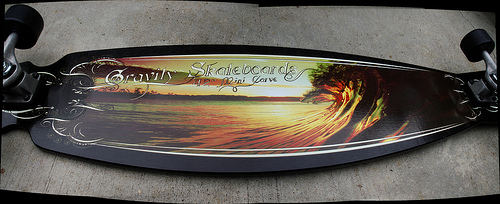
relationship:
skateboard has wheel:
[3, 4, 496, 176] [459, 26, 495, 63]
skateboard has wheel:
[3, 4, 496, 176] [4, 5, 45, 47]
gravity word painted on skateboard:
[105, 68, 181, 86] [3, 4, 496, 176]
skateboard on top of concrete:
[3, 4, 496, 176] [2, 3, 499, 203]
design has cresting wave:
[65, 57, 437, 138] [302, 62, 405, 147]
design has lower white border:
[65, 57, 437, 138] [43, 116, 473, 162]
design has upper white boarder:
[65, 57, 437, 138] [68, 50, 429, 94]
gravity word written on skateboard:
[105, 68, 181, 86] [3, 4, 496, 176]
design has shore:
[65, 57, 437, 138] [86, 90, 320, 104]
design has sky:
[65, 57, 437, 138] [85, 57, 338, 99]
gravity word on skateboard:
[105, 68, 181, 86] [3, 4, 496, 176]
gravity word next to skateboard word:
[105, 68, 181, 86] [185, 61, 302, 81]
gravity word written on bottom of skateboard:
[105, 68, 181, 86] [3, 4, 496, 176]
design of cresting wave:
[65, 57, 437, 138] [302, 62, 405, 147]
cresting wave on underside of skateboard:
[302, 62, 405, 147] [3, 4, 496, 176]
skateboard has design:
[3, 4, 496, 176] [65, 57, 437, 138]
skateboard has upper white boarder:
[3, 4, 496, 176] [68, 50, 429, 94]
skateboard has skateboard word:
[3, 4, 496, 176] [185, 61, 302, 81]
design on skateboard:
[65, 57, 437, 138] [3, 4, 496, 176]